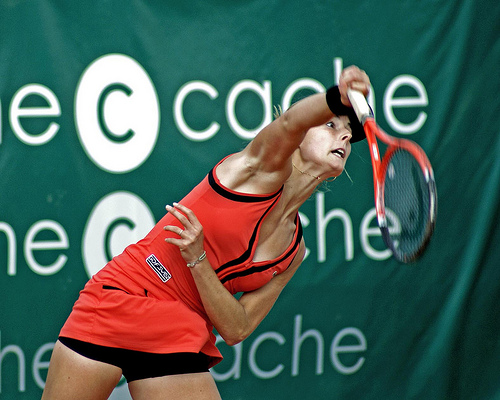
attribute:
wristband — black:
[328, 86, 348, 118]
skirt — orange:
[46, 252, 233, 378]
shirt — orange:
[124, 170, 320, 312]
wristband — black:
[326, 84, 343, 114]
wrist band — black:
[324, 82, 349, 115]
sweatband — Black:
[324, 81, 351, 121]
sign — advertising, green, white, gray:
[0, 3, 498, 398]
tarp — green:
[0, 0, 498, 398]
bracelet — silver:
[180, 245, 207, 272]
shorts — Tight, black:
[51, 325, 223, 385]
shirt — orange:
[184, 189, 281, 288]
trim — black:
[219, 189, 258, 209]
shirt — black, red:
[57, 151, 304, 369]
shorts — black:
[54, 326, 218, 381]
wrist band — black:
[324, 65, 368, 138]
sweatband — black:
[323, 87, 351, 112]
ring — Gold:
[177, 229, 185, 238]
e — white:
[8, 77, 67, 152]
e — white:
[378, 65, 433, 137]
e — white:
[19, 212, 73, 282]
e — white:
[353, 196, 405, 263]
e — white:
[328, 323, 374, 380]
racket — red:
[337, 66, 442, 266]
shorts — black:
[40, 335, 211, 383]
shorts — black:
[58, 333, 213, 381]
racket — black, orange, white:
[346, 84, 441, 266]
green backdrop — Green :
[445, 89, 489, 386]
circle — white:
[70, 50, 160, 172]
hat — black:
[341, 109, 364, 140]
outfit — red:
[53, 151, 301, 381]